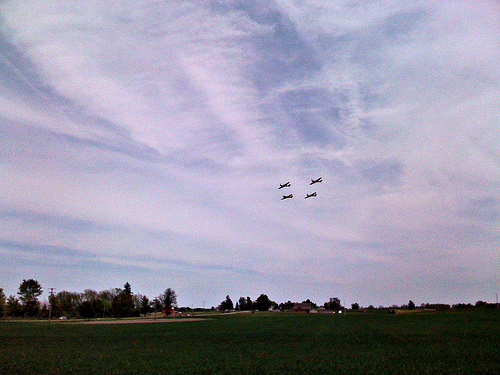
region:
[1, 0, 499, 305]
A background of cloudy sky.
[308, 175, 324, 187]
A far away airplane.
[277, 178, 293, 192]
An airplane in the distance.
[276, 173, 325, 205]
Four planes in the sky.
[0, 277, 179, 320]
An area of trees.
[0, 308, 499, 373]
A large green field.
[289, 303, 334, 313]
Some distant buildings.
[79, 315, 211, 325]
An area of dirt.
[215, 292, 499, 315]
A distant tree line.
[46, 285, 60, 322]
A distant power pole.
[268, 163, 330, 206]
Four jets in the sky.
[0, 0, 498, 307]
White clouds in the sky.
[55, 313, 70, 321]
Car in the background.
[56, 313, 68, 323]
Headlights on the car.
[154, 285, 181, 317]
Tree in the background.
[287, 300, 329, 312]
House in the background.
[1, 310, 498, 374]
Green grass covering the ground.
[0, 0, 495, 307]
blue sky in the background.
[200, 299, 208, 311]
Pole in the background.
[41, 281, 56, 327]
Telephone pole beside the road.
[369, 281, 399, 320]
white snow on hill side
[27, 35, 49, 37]
Black bird in the sky with clouds.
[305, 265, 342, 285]
Black bird in the sky with clouds.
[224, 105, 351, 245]
these are four planes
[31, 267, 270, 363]
these are old trees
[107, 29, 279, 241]
this is a cloudy day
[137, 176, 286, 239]
this is a cloud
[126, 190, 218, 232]
the cloud is white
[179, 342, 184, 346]
this is a patch of green grass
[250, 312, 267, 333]
there are no people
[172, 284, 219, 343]
there are no animals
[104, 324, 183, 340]
this is a patch of dirt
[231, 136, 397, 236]
planes in the sky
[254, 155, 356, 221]
four planes in sky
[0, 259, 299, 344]
trees in the distance